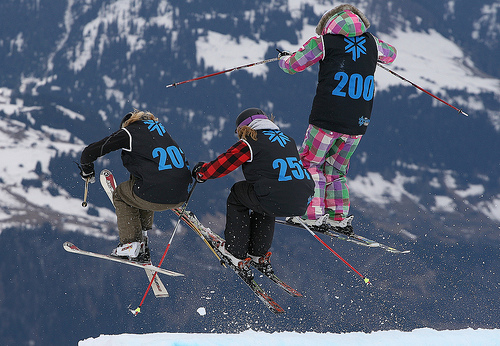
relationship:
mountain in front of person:
[1, 0, 495, 345] [79, 107, 191, 260]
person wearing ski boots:
[277, 5, 401, 230] [287, 213, 352, 234]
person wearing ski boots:
[191, 110, 313, 270] [213, 239, 271, 269]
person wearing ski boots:
[79, 107, 191, 260] [112, 241, 146, 262]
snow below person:
[78, 324, 496, 345] [79, 107, 191, 260]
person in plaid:
[191, 110, 313, 270] [197, 140, 249, 183]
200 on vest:
[330, 72, 374, 100] [309, 33, 376, 134]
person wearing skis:
[277, 5, 401, 230] [276, 206, 411, 255]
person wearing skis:
[191, 110, 313, 270] [171, 206, 300, 311]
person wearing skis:
[79, 107, 191, 260] [62, 169, 184, 298]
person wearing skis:
[79, 107, 191, 260] [276, 206, 411, 255]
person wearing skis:
[79, 107, 191, 260] [171, 206, 300, 311]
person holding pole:
[277, 5, 401, 230] [167, 53, 287, 89]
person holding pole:
[277, 5, 401, 230] [376, 62, 464, 115]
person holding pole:
[191, 110, 313, 270] [135, 177, 204, 310]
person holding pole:
[191, 110, 313, 270] [293, 218, 368, 286]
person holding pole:
[79, 107, 191, 260] [81, 177, 89, 208]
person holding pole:
[79, 107, 191, 260] [167, 53, 287, 89]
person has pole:
[277, 5, 401, 230] [376, 62, 464, 115]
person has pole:
[277, 5, 401, 230] [167, 53, 287, 89]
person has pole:
[191, 110, 313, 270] [293, 218, 368, 286]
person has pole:
[191, 110, 313, 270] [135, 177, 204, 310]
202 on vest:
[151, 147, 185, 169] [123, 111, 192, 205]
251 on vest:
[271, 154, 311, 183] [240, 128, 313, 215]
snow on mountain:
[78, 324, 496, 345] [1, 0, 495, 345]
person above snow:
[79, 107, 191, 260] [78, 324, 496, 345]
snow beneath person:
[78, 324, 496, 345] [79, 107, 191, 260]